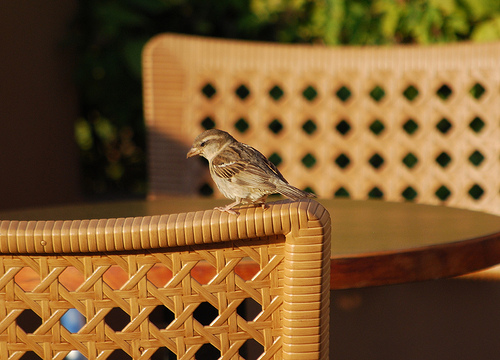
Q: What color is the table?
A: Brown.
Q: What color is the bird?
A: Brown.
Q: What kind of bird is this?
A: House Sparrow.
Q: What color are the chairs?
A: Brown.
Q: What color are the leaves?
A: Green.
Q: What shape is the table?
A: Round.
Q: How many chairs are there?
A: Two.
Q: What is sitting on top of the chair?
A: Bird.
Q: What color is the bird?
A: Brown.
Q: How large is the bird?
A: Small.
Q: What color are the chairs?
A: Tan.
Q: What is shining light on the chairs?
A: Sun.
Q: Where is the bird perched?
A: Chair.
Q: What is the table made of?
A: Wood.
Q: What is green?
A: Leaves.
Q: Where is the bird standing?
A: On a outdoor chair.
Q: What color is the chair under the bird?
A: Brown.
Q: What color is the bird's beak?
A: Brown.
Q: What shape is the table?
A: Round.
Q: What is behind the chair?
A: Vegetation.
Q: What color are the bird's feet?
A: Brown.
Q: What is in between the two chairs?
A: A table.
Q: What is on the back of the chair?
A: A bird.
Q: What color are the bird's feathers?
A: Brown.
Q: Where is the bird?
A: Sitting on a chair.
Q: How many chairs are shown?
A: Two.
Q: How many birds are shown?
A: One.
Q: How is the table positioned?
A: Between the two chairs.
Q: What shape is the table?
A: Round.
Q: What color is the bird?
A: Brown.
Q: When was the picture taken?
A: During daylight hours.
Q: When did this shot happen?
A: Daytime.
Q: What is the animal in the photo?
A: Bird.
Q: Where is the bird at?
A: Chair.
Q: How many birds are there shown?
A: 1.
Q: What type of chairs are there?
A: Woven.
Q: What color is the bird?
A: Brown.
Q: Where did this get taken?
A: In a backyard.